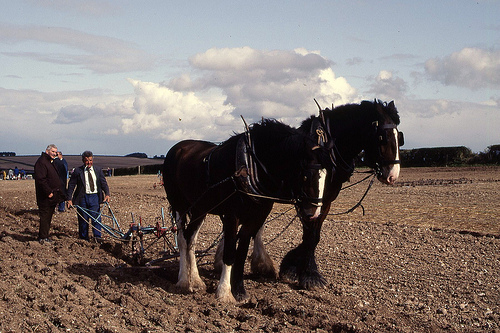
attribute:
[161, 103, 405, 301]
horses — plowing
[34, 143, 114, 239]
farmers — dressed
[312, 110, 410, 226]
faces — white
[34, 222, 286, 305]
soil — rocky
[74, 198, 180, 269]
plow — blue, metal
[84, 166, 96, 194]
shirt — white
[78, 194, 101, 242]
jeans — blue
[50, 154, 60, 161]
beard — gray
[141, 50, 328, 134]
clouds — fluffy, white